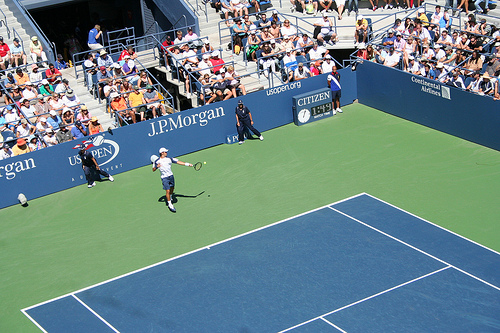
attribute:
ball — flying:
[201, 157, 207, 164]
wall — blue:
[0, 67, 472, 199]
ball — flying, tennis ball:
[200, 158, 211, 165]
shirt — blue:
[145, 143, 206, 218]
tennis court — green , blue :
[10, 172, 499, 332]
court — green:
[289, 128, 440, 190]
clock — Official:
[292, 89, 343, 128]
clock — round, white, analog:
[286, 89, 340, 125]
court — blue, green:
[263, 164, 415, 331]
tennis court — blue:
[21, 193, 495, 331]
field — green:
[9, 108, 493, 332]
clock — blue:
[287, 85, 340, 127]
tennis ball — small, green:
[193, 159, 213, 185]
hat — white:
[158, 145, 170, 153]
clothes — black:
[239, 112, 253, 132]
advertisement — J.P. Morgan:
[148, 102, 228, 137]